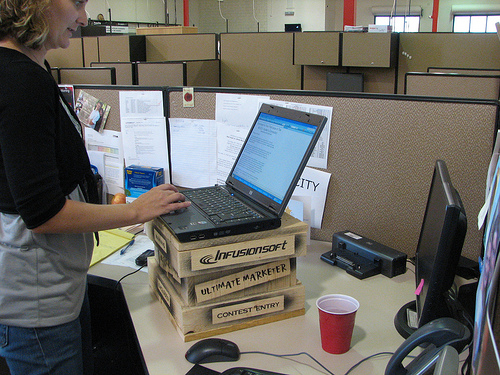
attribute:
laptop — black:
[156, 99, 326, 247]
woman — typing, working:
[2, 1, 187, 374]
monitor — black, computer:
[396, 161, 476, 340]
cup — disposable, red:
[316, 293, 364, 361]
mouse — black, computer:
[182, 336, 248, 367]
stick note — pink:
[416, 278, 427, 299]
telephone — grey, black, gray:
[384, 317, 471, 374]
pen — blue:
[117, 235, 137, 254]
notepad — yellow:
[93, 229, 136, 272]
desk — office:
[76, 88, 499, 374]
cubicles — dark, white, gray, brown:
[55, 0, 498, 344]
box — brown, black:
[154, 227, 310, 333]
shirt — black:
[4, 43, 96, 219]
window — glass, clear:
[364, 1, 500, 33]